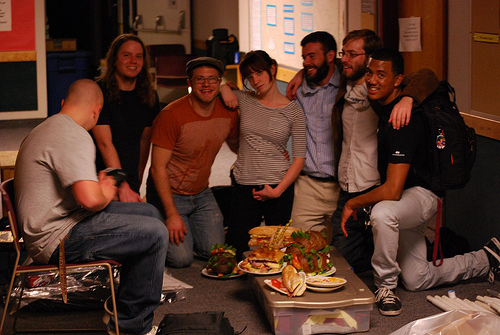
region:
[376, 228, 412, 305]
This man is wearing light-colored jeans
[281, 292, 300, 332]
There is a plastic container here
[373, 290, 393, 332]
This man is wearing a pair of athletic shoes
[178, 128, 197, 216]
This man is wearing a red t-shirt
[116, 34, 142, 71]
This person has long hair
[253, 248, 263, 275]
There is a large sandwich here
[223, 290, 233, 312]
There is gray flooring visible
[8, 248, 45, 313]
There is a brown chair that is here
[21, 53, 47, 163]
There is a bulletin board in the back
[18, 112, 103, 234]
man wearing gray shirt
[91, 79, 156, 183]
woman wearing a black shirt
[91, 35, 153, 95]
woman with blonde hair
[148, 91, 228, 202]
man wearing a brown shirt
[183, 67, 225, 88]
man wearing reading glasses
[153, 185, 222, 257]
man wearing blue jeans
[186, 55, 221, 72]
man wearing a brown hat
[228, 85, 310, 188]
woman wearing a striped shirt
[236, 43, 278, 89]
woman with brown hair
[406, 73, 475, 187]
man wearing a back pack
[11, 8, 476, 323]
Some people are inside a house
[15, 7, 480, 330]
Some people are having a celebration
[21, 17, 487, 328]
Some workers are enjoying a meal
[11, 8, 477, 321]
The people are all close friends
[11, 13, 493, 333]
The people are all roommates in college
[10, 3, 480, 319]
The people are men and women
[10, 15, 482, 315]
The people are having a great time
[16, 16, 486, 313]
The people are out in the daytime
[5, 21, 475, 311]
The people are having a reunion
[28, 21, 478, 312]
The people are enjoying the day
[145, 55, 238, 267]
a young man kneeling on floor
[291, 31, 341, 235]
a young man kneeling on floor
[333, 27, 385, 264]
a young man kneeling on floor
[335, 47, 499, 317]
a young man kneeling on floor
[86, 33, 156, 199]
a young man kneeling on floor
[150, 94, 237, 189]
a man's red t-shirt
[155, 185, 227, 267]
a pair of blue jeans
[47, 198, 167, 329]
a pair of blue jeans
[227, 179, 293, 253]
a pair of black jeans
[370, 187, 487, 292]
a pair of white jeans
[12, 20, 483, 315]
Group of friends at party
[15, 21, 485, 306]
Group of friend pose for a picture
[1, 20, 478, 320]
Group of friends pose in front of table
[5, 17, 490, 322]
Group of friends smile for a picture in front of food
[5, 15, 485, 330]
Women and men pose in a living room for a picture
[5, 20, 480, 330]
Friends hold each other's shoulders for picture pose.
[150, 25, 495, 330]
Couple pose for a picture with friends on side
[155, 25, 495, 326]
Male and female couple pose with friends for picture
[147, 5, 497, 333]
Man in red shirt and women with grey shirt pose with friends